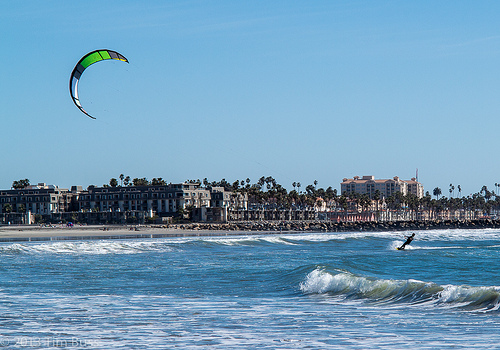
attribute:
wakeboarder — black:
[385, 220, 432, 252]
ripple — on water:
[164, 311, 267, 344]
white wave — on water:
[300, 268, 498, 310]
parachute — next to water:
[37, 33, 154, 146]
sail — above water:
[63, 40, 133, 126]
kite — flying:
[68, 46, 131, 121]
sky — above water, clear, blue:
[4, 0, 498, 197]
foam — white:
[19, 241, 152, 259]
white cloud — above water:
[191, 15, 248, 33]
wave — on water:
[250, 223, 335, 253]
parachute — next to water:
[45, 25, 444, 271]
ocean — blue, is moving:
[1, 220, 498, 347]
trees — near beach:
[251, 174, 268, 193]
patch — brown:
[84, 220, 99, 227]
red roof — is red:
[321, 175, 425, 217]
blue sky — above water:
[292, 53, 402, 134]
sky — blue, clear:
[5, 6, 499, 176]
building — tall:
[325, 166, 445, 219]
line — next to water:
[10, 226, 498, 234]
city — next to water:
[0, 164, 498, 228]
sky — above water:
[167, 27, 447, 168]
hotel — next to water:
[335, 172, 427, 213]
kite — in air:
[62, 43, 134, 120]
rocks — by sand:
[291, 219, 360, 231]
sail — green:
[66, 47, 130, 127]